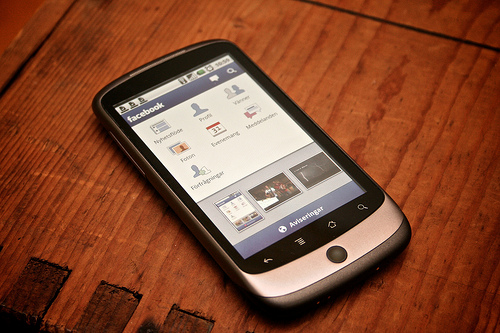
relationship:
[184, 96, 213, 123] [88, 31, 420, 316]
icon on cell phone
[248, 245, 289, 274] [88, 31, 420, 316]
button on cell phone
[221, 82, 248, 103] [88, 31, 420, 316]
icon on cell phone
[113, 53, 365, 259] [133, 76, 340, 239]
screen shows facebook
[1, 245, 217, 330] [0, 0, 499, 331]
marks on table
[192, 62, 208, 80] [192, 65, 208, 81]
symbol display battery life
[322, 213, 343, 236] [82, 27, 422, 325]
button on mobile phone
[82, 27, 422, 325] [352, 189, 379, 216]
mobile phone has button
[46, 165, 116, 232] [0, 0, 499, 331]
patch on table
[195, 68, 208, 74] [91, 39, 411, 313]
battery indicator on phone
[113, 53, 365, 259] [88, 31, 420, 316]
screen on cell phone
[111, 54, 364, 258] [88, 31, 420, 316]
image on cell phone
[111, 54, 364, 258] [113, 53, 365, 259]
image on screen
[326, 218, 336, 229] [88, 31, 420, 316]
home button on cell phone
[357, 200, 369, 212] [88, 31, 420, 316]
search button on cell phone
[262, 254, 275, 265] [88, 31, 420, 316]
back button on cell phone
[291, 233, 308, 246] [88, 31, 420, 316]
menu button on cell phone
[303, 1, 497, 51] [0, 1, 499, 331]
crack in wood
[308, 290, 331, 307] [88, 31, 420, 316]
holes in cell phone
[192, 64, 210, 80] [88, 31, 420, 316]
battery icon on cell phone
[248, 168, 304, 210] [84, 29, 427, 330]
picture on phone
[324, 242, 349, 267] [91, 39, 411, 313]
circle on phone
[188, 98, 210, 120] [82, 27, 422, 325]
profile button on mobile phone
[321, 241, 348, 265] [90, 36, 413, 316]
microphone on bottom of cellphone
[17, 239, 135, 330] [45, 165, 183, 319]
strip on table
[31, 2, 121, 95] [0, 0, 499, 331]
spot on table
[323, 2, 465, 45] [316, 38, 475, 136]
black-separation line in wood table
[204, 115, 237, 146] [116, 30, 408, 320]
application on a cellphone